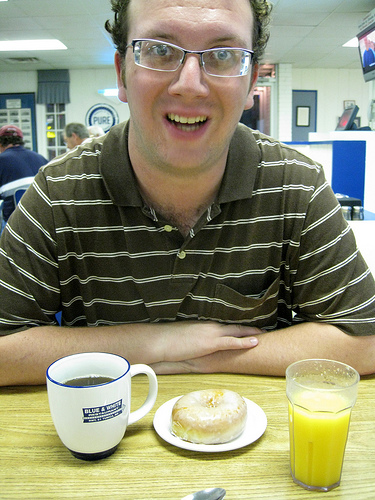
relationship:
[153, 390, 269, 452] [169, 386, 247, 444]
plate with a donut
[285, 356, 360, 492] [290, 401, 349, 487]
glass with juice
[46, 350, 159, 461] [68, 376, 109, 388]
mug of coffee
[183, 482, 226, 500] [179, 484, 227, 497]
tip of silver spoon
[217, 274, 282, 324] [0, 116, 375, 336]
pocket on a polo shirt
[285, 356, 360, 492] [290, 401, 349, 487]
glass of juice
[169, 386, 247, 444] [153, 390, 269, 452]
donut on plate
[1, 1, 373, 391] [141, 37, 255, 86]
man wearing eyeglasses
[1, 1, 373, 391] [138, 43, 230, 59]
man has eyes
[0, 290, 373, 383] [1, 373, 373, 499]
arms on table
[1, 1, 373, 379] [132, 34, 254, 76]
man wearing eyeglasses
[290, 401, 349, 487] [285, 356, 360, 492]
juice inside glass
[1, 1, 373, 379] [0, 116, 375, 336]
man wearing polo shirt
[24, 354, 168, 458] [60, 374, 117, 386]
mug of coffee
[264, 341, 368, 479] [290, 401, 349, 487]
glass of juice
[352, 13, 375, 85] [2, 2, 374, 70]
television hanging from ceiling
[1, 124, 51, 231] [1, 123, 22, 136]
man in hat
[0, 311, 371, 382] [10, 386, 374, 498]
arms folded on table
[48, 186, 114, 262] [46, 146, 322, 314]
stripes on shirt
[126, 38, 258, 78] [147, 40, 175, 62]
eyeglasses over eye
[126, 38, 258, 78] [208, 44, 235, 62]
eyeglasses over eye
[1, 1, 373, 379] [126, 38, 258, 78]
man wearing eyeglasses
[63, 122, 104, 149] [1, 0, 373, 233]
person in background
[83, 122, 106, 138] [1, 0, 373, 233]
person in background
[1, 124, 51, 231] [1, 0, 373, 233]
man in background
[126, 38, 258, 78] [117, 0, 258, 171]
eyeglasses of face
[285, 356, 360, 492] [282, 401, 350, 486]
glass of juice